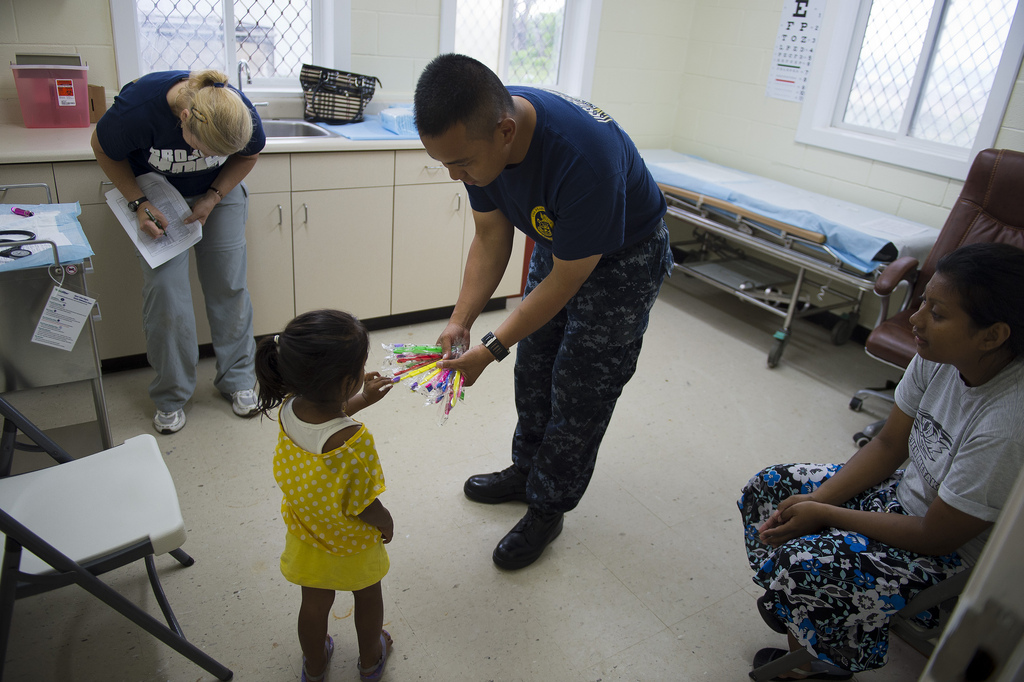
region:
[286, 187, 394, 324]
cabinet has a door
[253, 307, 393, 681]
A small brown haired girl in yellow.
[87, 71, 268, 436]
A blonde woman bending over wtih a piece of paper.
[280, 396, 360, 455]
White undershirt on a girl.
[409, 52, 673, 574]
A black haired man bending down in a blue shirt.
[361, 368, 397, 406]
A little girls left hand.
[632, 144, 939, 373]
A bed up against the wall.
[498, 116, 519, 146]
A mans left ear.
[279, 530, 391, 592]
Yellow skirt on a little girl.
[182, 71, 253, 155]
A woman's blonde hair.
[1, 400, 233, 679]
Dark grey chair with white seat.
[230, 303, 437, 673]
A young child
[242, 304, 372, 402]
The black hair on the child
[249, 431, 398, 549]
Thee yellow shirt on the child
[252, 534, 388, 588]
The yellow skirt on the child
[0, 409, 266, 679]
The empty white chair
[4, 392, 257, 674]
A white chair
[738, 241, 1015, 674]
The woman sitting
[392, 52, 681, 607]
man handing out toothbrush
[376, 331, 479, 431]
man holding handful of toothbrush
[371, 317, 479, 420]
toothbrush are very colorful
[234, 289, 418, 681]
little girl picking out toothbrush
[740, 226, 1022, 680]
woman sitting in chair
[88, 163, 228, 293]
woman writing on paper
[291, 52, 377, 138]
purse on sink counter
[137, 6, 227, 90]
building has a window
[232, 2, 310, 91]
building has a window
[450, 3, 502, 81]
building has a window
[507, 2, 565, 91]
building has a window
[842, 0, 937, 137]
building has a window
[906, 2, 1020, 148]
building has a window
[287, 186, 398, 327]
cabinet has a door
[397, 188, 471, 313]
cabinet has a door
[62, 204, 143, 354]
cabinet has a door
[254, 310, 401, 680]
the little girl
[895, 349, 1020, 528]
the white t-shirt of the woman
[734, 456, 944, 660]
the blue and white skirt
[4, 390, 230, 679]
the white and black chair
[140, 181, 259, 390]
the grey pants of the woman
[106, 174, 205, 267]
the white piece of paper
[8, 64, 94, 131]
the red plastic box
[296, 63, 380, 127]
the black and white bag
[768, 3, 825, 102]
the eyechart on the wall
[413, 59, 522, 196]
head of a man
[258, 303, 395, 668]
the girl is young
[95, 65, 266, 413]
a woman is standing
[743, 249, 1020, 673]
a person is sitting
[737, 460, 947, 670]
blue and white dress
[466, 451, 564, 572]
the shoes are black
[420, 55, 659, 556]
A person is standing up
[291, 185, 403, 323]
A door for a cabinet.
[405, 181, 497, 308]
A door for a cabinet.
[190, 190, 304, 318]
A door for a cabinet.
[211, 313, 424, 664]
A person is standing up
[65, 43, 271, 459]
A person is standing up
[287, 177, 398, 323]
A door for a cabinet.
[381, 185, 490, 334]
A door for a cabinet.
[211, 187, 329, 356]
A door for a cabinet.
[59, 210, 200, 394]
A door for a cabinet.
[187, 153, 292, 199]
A door for a cabinet.